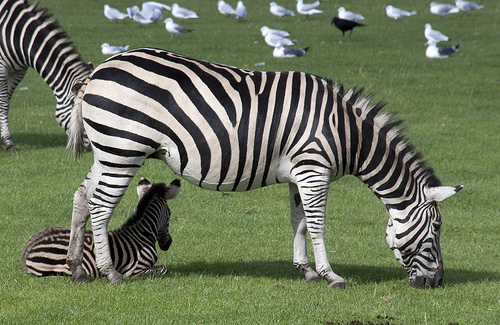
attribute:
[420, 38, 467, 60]
bird — white, gray, resting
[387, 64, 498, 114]
grass — green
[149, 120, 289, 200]
belly — bulky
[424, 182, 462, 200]
ear — white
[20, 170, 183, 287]
zebra — baby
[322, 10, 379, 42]
bird — black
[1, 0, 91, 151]
zebra — grazing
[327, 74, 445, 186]
mane hair — black, white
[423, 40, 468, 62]
bird — white, gray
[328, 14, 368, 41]
bird — black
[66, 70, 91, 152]
tail — short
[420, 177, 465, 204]
ear — pointy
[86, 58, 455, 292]
zebra — white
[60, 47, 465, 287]
stripes — black, white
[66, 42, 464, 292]
zebra — black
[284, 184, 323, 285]
spot — small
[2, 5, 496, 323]
grass — green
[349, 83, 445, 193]
hair — black